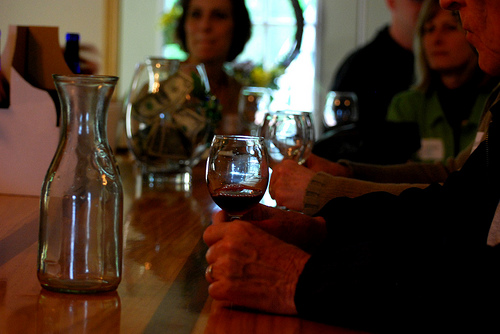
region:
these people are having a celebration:
[9, 6, 486, 303]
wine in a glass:
[196, 121, 281, 220]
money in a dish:
[128, 55, 220, 205]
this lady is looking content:
[165, 5, 262, 65]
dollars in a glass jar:
[107, 55, 244, 176]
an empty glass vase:
[28, 70, 145, 297]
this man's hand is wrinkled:
[170, 228, 320, 319]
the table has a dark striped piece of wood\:
[126, 203, 221, 330]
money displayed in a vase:
[131, 47, 193, 178]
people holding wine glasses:
[203, 93, 380, 205]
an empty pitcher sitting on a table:
[58, 84, 150, 319]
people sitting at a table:
[313, 26, 488, 218]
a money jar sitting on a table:
[126, 57, 201, 185]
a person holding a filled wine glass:
[161, 121, 281, 272]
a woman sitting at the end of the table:
[163, 3, 268, 56]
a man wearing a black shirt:
[302, 224, 389, 331]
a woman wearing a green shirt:
[381, 79, 455, 146]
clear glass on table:
[205, 130, 267, 212]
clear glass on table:
[264, 116, 304, 165]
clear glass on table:
[294, 110, 314, 167]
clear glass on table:
[322, 93, 357, 125]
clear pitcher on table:
[37, 72, 128, 298]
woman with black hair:
[174, 2, 251, 65]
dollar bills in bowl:
[128, 71, 213, 163]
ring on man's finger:
[205, 262, 216, 280]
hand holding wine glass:
[264, 162, 323, 207]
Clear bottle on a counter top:
[40, 75, 127, 295]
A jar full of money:
[126, 54, 215, 171]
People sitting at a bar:
[239, 0, 499, 322]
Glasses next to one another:
[262, 104, 316, 169]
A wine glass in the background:
[318, 83, 362, 128]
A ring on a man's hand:
[206, 260, 216, 279]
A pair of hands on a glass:
[198, 129, 314, 312]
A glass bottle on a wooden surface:
[36, 73, 124, 293]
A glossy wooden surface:
[1, 186, 311, 331]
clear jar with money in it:
[126, 57, 200, 176]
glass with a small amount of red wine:
[207, 135, 267, 218]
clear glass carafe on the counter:
[22, 52, 159, 292]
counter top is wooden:
[134, 250, 196, 325]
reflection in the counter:
[131, 195, 191, 296]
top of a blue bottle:
[59, 27, 87, 69]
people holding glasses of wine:
[179, 107, 411, 282]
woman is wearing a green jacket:
[393, 85, 490, 178]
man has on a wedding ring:
[199, 259, 218, 281]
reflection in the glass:
[53, 185, 104, 277]